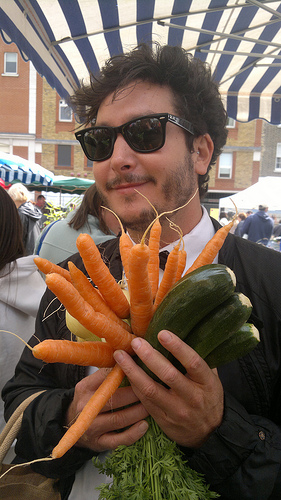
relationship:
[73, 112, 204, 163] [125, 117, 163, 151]
sunglasses reflect crowd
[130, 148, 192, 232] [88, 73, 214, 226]
beard on face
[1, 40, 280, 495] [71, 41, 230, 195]
man has hair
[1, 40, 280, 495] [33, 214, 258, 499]
man holding vegetables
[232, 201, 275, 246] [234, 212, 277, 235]
man wearing sweater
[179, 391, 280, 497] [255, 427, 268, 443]
sleeve has button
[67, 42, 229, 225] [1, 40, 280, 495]
head of man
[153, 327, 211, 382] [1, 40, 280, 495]
finger of man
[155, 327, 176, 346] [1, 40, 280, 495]
finger nail of man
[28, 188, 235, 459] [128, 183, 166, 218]
carrots have stems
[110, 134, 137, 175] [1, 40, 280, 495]
nose of man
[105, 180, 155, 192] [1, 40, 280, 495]
mouth of man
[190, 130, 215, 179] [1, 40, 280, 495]
ear of man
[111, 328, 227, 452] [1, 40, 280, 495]
hand of man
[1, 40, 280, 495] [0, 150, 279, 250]
man at market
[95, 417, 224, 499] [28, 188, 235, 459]
greens of carrots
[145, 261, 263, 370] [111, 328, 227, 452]
squash in hand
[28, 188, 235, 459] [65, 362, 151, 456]
carrots in hand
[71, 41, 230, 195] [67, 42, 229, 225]
hair on head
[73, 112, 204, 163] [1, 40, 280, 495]
eyeglasses on man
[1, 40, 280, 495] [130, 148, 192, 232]
man with beard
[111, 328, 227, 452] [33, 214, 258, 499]
hands holding vegetables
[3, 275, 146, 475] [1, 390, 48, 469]
arm with handle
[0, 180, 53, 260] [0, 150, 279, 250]
shoppers at market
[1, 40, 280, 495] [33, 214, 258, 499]
man holds vegetables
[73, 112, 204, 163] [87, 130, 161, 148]
sunglasses on eyes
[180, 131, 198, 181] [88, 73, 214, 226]
sideburns on face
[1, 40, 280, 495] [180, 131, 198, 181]
man has sideburns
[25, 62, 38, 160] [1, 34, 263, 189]
border on building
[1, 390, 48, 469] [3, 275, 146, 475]
handle on arm